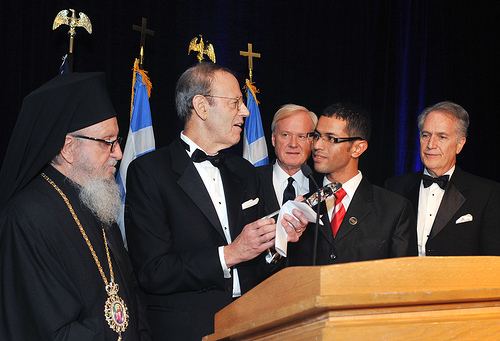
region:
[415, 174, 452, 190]
the bowtie is black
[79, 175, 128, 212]
the beard is long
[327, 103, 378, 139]
the hair is black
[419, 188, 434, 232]
the shirt is white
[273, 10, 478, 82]
the curtain is blue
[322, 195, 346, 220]
the tie is red and golden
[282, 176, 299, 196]
the tie is black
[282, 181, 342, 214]
the award is made of glass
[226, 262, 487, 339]
the podium is made of wood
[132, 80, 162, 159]
the flag is blue and white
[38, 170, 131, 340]
priest wearing large gold necklace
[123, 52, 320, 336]
man in black tuxedo at celebration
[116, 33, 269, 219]
blue and white flags on top of cross poles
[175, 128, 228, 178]
man wearing black bow tie on neck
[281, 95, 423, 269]
black man in red tie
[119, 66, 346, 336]
man wearing glasses ar podium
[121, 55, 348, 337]
man at podium holding glass award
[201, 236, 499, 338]
large oak colored podium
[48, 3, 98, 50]
gold eagle on top of flag pole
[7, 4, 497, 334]
black curtains behind men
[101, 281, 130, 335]
Large round medallion around the man's neck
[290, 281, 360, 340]
Corner of the brown wooden podium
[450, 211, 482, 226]
Handkerchief in the pocket of the man on the right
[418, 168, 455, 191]
Bowtie of the man on the right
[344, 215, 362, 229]
Round pin on the lapel of the African American man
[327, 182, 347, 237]
African American man's red tie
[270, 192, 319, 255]
White item the gentleman at the podium is holding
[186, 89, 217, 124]
Right ear of the man at the podium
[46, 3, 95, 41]
Eagle against the curtains in the background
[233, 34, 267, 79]
Gold cross above the flag in the background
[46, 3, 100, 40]
eagle atop flag pole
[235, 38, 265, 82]
cross atop flag pole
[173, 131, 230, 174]
black bow tie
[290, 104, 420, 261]
young man wearing red tie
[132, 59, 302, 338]
man presenting glass object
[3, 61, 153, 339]
man in black wearing colored medallion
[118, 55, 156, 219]
blue and white flag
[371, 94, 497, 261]
man wearing suit and bow tie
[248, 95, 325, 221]
man in suit with blonde hair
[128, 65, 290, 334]
man in suit wearing glasses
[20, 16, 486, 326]
A ceremony.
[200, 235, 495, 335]
A podium made from wood.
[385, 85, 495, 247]
The man is wearing a suit.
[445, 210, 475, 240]
A handkerchief in his pocket.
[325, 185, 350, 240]
The man is wearing a red tie.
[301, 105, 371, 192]
The man is wearing glasses.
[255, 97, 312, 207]
Chris Matthews.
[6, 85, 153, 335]
An orthodox priest.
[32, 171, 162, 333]
The man is wearing a large gold necklace.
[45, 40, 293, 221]
Four flags are behind the men.